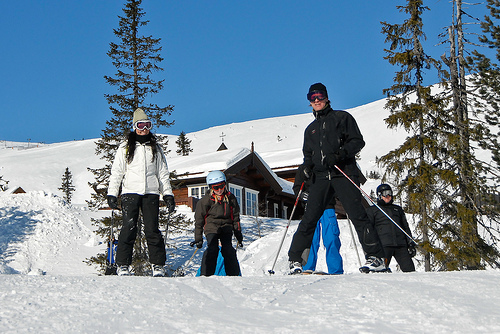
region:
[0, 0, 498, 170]
THE BLUE SKY IS VERY CLEAR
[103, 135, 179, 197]
THE WOMAN IS WEARING A JACKET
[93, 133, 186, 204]
THE WOMAN'S JACKET IS WHITE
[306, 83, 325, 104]
THE MAN IS WEARING A HAT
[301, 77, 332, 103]
THE MAN'S HAT IS BLACK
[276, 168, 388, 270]
THE KID IS WEARING BLACK PANTS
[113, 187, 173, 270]
THE WOMAN IS WEARING BLACK PANTS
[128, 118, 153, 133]
THE WOMAN IS WEARING GOGGLES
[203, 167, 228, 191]
THE KID IS WEARING A WHITE HELMET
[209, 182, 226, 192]
THE KID IS WEARING GOGGLES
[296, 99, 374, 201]
THE MAN IS WEARING A JACKET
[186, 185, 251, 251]
THE KID IS WEARING A JACKET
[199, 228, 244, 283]
THE KID IS WEARING BLACK PANTS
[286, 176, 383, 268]
THE MAN IS WEARING BLACK PANTS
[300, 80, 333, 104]
THE MAN IS WEARING A BLACK HAT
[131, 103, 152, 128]
THE WOMAN IS WEARING A WHITE HAT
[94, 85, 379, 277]
THE FAMILY IS STANDING ON THE SNOWY HILL TOGETHER FOR A PICTURE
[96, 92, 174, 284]
woman wearing white jacket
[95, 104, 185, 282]
woman wearing white boots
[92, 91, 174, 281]
woman wearing black pants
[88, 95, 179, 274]
woman wearing white goggles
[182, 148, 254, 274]
girl wearing red goggles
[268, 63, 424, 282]
man wearing black coat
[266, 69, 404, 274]
man wearing black pants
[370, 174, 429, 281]
man wearing black pants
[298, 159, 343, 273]
man wearing blue pants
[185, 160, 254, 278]
girl wearing white helmet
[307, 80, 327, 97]
the man is wearing a hat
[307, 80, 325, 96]
the hat is black in color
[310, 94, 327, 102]
the man is wearing sunglasses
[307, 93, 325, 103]
the sunglasses are black in color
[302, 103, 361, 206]
the man is wearing a coat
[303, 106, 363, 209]
the coat is black in color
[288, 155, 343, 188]
the man is wearing gloves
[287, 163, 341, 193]
the gloves are black in color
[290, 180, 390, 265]
the man is wearing black pants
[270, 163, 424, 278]
the man is holding ski poles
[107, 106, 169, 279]
woman skier in white jacket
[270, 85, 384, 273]
skier with black jacket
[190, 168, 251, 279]
child in white helmet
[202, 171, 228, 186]
white helmet on girl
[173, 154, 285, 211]
building behind skiers on hill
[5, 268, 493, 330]
white slope of snow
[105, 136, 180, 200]
white jacket on woman skier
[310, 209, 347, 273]
blue pants on skier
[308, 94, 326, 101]
ski goggle on man in black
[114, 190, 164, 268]
black pants on woman skier